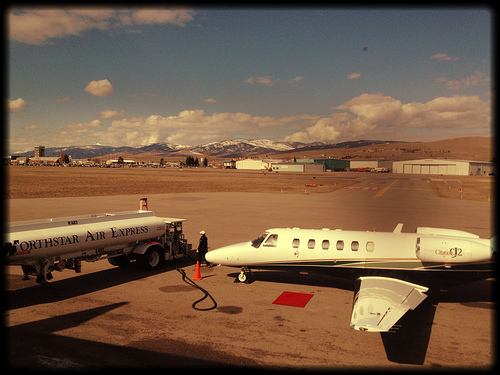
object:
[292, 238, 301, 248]
windows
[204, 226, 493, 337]
plane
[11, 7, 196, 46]
clouds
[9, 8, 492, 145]
sky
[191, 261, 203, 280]
cone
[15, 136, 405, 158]
mountains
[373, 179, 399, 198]
lines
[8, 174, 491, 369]
tarmac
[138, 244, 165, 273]
tire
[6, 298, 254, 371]
shadows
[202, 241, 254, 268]
nose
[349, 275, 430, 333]
wing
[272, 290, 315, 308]
mat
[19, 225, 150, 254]
name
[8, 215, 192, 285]
truck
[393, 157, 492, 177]
building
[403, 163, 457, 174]
doors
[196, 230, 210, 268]
person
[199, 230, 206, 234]
hat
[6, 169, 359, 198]
grass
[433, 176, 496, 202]
grass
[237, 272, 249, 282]
tire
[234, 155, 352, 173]
buildings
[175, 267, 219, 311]
gas hose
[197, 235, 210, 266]
clothing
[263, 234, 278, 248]
window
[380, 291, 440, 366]
shadow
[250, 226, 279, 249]
cockpit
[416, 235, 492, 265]
engine